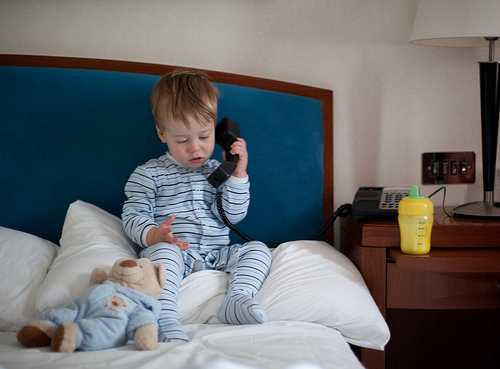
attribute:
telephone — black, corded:
[208, 115, 422, 252]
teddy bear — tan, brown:
[13, 253, 168, 353]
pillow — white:
[33, 197, 392, 354]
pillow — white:
[1, 222, 63, 335]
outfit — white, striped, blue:
[118, 151, 270, 342]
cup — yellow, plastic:
[393, 183, 435, 256]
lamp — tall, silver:
[407, 0, 499, 224]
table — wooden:
[335, 200, 498, 368]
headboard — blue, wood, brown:
[0, 51, 336, 252]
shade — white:
[404, 0, 498, 52]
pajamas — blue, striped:
[45, 278, 161, 350]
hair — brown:
[148, 65, 219, 133]